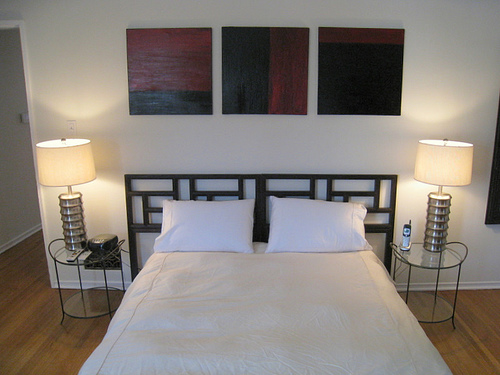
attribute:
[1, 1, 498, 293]
wall — white, lit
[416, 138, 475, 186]
lamp — white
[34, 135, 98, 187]
lamp — white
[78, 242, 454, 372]
sheet — white, cream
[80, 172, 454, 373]
bed — wooden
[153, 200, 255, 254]
pillow — white, fluffy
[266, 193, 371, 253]
pillow — white, fluffy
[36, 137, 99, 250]
lamp — silver, decorative, shiny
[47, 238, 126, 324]
table — glass, cirular, metal, round, clear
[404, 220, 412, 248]
phone — wireless, cordless, white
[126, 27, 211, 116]
picture — red, black, art work, large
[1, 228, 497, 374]
floor — wooden, brown, wood, lined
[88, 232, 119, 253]
clock — radio, silver, black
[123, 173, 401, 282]
headboard — wooden, rectangular, wood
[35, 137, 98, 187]
shade — cream, white, round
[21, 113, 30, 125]
panel — white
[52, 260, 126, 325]
legs — small